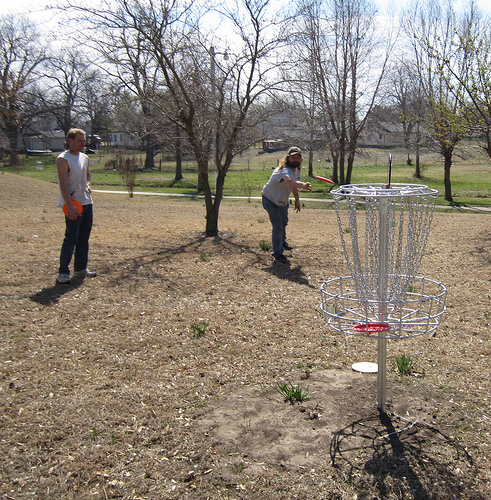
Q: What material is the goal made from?
A: Metal.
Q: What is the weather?
A: Sunny.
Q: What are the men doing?
A: Playing with frisbees.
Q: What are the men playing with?
A: Frisbees.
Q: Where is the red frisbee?
A: In the cage.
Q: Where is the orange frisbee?
A: In the left man's hand.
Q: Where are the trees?
A: Behind the men.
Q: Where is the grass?
A: On the ground.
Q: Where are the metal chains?
A: On the frisbee cage.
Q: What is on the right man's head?
A: A hat.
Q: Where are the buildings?
A: Behind the trees.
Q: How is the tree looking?
A: Dry.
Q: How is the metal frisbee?
A: Large.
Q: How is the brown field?
A: Dried.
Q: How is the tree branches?
A: Dried.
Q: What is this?
A: Trees.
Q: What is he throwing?
A: Frisbee.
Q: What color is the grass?
A: Green.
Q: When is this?
A: Daytime.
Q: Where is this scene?
A: At a park.